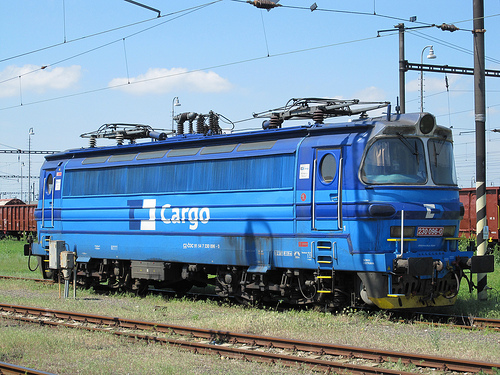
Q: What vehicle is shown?
A: A train.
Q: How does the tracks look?
A: Rusty.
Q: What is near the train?
A: Grass.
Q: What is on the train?
A: Engine.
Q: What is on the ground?
A: Rusty tracks.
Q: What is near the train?
A: Rusty railroad tracks.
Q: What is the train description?
A: Blue.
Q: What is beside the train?
A: A pole.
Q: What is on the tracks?
A: A train.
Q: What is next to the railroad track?
A: Grass.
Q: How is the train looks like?
A: Cargo.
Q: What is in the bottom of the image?
A: Dark pole.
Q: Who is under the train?
A: No one.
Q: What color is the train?
A: Blu.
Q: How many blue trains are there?
A: One.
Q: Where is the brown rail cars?
A: Behind blue train.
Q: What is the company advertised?
A: Cargo.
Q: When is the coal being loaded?
A: No coal.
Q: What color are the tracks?
A: Brown.